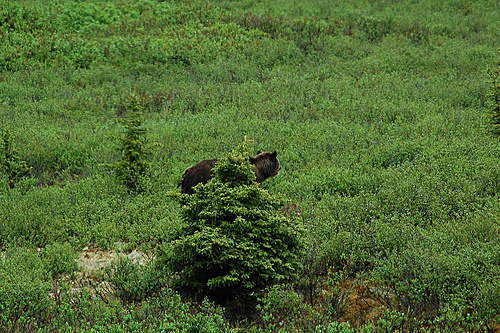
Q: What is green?
A: The plants.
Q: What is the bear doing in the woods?
A: Looking for food.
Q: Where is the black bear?
A: In the woods.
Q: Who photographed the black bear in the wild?
A: Hunter.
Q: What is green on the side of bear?
A: Small tree.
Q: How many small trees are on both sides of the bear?
A: 2.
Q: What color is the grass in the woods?
A: Green.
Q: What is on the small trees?
A: Leaves.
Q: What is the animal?
A: Bear.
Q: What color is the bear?
A: Black.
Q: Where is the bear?
A: In a field.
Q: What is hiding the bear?
A: Small tree.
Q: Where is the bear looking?
A: Away from the camera.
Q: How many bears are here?
A: One.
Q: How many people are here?
A: None.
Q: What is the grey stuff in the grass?
A: Dirt.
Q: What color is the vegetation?
A: Green.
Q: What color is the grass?
A: Green.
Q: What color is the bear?
A: Black.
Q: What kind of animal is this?
A: Bear.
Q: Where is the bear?
A: Field.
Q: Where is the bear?
A: In the forest.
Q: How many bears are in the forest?
A: One.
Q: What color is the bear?
A: Black.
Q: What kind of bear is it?
A: A wild bear.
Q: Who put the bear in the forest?
A: No one.